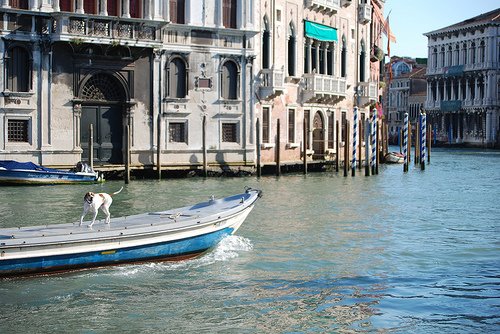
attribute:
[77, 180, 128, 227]
dog — brown, white, tan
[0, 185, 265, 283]
boat — blue, white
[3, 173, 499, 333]
water — large extension, clear, calm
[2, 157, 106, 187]
boat — blue, white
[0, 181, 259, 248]
tarp — blue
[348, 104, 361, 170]
pole — blue, white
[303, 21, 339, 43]
awning — aqua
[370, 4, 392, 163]
building — pink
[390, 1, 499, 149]
building — big 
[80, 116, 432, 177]
fence — wooden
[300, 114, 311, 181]
pole — brown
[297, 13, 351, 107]
balcony — white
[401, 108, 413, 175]
post — striped, stripped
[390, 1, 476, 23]
sky — blue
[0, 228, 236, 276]
bottom — blue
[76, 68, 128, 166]
doors — dark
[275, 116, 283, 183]
post — woode